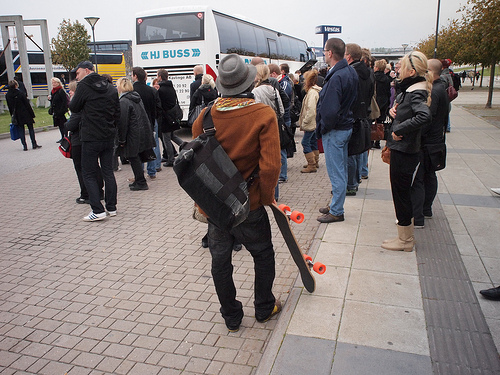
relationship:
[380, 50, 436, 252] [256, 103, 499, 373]
lady on sidewalk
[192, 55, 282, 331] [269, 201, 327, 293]
man holding board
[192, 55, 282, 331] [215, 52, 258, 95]
man wearing cap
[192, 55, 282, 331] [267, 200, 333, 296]
man holding board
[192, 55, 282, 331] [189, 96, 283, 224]
man wearing coat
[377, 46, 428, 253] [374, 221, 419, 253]
lady wearing boots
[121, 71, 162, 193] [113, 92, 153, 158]
woman in jacket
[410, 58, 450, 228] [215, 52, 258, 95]
man with cap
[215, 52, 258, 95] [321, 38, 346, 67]
cap on head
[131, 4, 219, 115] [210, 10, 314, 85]
back and side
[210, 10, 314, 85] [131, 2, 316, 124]
side of bus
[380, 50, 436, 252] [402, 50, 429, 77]
lady with hair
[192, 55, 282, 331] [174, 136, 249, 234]
man with bag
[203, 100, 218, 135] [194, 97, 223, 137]
strap on shoulder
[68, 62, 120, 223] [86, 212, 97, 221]
man with stripes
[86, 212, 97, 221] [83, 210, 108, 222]
stripes on sneaker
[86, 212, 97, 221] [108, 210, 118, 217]
stripes on sneaker